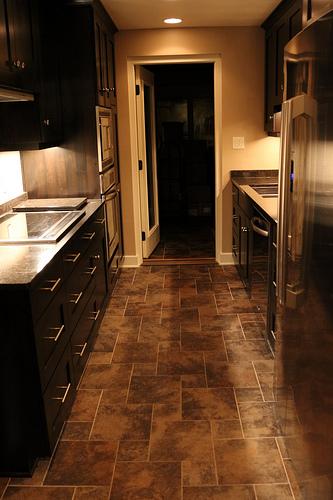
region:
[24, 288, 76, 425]
row of drawers in kitchen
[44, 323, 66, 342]
handle to a drawer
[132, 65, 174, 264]
door that is ajar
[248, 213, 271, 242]
handle to an appliance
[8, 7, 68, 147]
cabinet above the counter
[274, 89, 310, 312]
handle to the refrigerator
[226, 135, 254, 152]
power square on the wall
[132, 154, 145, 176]
middle hinge on the door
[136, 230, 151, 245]
lower hinge on the door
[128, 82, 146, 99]
upper hinge on the door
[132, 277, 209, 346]
the floor is tile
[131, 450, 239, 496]
the floor is brown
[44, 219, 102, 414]
the cabinets have handles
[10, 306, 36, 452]
the cabinets are black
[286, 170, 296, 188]
the light is blue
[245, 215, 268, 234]
the dishwasher has a handle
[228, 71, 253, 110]
the wall is beige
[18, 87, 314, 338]
the kitchen is nice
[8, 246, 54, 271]
the counter top is marble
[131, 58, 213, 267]
the door is open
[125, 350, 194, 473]
Brown tiles on floor.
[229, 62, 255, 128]
Walls are painted tan.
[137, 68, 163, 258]
The open door in the kitchen.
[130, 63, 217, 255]
The doorway in the kitchen area.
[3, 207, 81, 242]
The flat stove range.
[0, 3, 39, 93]
The cabinets above the stove.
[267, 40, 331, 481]
The chrome colored fridge.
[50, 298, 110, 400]
The handles on the bottom row of the cabinets below the stove.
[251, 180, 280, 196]
The sink on the right side.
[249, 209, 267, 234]
The handle on the dishwasher.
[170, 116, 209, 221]
The stack of boxes in the next room through the doorway.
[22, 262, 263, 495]
The brown and tan tiles on the floor.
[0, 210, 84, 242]
the ceramic stove top in the kitchen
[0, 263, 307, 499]
the tiles on the kitchen floor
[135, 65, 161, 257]
the door in the kitchen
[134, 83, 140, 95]
the hinge on the door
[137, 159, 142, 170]
the hinge on the door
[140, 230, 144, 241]
the hinge on the door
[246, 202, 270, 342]
the dishwasher under the counter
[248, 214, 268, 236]
the handle on the dishwasher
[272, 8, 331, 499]
the refrigerator in the kitchen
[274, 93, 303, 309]
the handles on the refrigerator